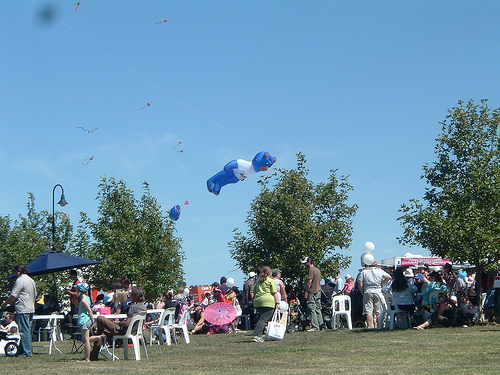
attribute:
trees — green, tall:
[13, 100, 499, 273]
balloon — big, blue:
[165, 154, 279, 224]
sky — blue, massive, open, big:
[2, 3, 495, 220]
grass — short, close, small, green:
[0, 319, 499, 375]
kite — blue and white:
[169, 134, 288, 222]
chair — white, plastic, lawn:
[124, 315, 153, 354]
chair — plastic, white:
[117, 319, 157, 366]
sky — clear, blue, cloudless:
[130, 0, 306, 99]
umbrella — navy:
[27, 253, 81, 281]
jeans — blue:
[1, 296, 51, 353]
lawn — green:
[323, 353, 392, 370]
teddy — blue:
[183, 136, 288, 200]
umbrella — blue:
[29, 249, 103, 279]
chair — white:
[126, 317, 157, 360]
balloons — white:
[354, 246, 380, 268]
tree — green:
[255, 159, 375, 255]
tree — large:
[243, 165, 391, 252]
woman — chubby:
[244, 292, 298, 322]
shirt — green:
[247, 271, 272, 310]